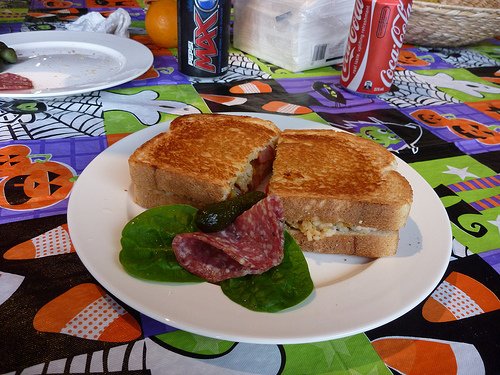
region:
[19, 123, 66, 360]
Halloween style table cloth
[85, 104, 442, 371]
A plate of food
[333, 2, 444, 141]
Can of coca cola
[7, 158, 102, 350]
Pumpkin and candy corn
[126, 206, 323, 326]
Lunch meat on a bed of lettuce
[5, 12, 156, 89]
A nearly empty plate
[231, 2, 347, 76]
A stack of napkins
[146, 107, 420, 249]
A toasted sandwich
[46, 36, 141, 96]
White plate with crumbs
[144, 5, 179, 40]
An orange fruit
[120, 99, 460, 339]
A SANDWICH ON A PLATE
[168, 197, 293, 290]
A PICKLE AND SALAMI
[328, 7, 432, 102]
A CAN OF COKE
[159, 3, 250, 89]
A CAN OF PEPSI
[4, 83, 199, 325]
A HALLOWEEN TABLE CLOTH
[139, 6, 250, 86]
AN ORANGE NEXT TO A CAN OF PEPSI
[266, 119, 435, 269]
A HALF OF SANDWICH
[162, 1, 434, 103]
TWO CANS ON THE TABLE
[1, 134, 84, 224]
A PICTURE OF A PUMPKIN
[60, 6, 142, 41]
A USED NAPKIN ON THE TABLE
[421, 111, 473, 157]
part of a cloth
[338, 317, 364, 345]
edge of a plate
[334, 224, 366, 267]
edge of a bread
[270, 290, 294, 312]
edge of a leaf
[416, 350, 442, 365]
part of an orange colour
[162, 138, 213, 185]
surface of a bread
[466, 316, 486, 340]
part of a black part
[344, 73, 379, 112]
base of a can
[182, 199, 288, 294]
the meat is pink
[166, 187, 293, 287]
the meat has spots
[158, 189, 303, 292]
the fat is white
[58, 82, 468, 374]
the plate is white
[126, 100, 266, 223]
the bread is brown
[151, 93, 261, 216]
the bread is toasted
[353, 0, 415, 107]
the can is red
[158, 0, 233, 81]
the can is black and red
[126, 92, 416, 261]
there are two sandwiches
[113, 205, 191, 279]
the leaf is green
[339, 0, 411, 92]
can of Coca Cola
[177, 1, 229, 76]
can of pepsi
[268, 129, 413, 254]
half of sandwich on right of plate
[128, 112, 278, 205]
half of sandwich on left of plate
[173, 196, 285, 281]
folded baloney on plate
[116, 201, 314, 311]
two green leaves on plate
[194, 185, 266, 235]
small, green pickle on plate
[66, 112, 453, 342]
plate with sandwich is white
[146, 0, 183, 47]
an orange behind Pepsi can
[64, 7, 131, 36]
crumpled, white napkin